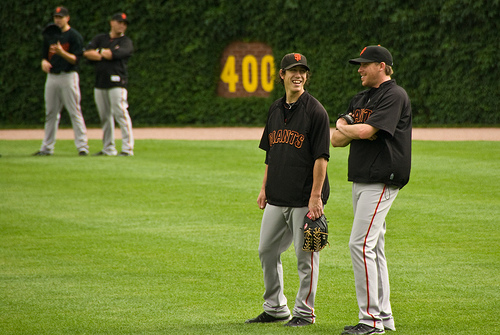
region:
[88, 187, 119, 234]
section of a field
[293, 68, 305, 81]
face of a boy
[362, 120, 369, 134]
part of an elbow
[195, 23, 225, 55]
part of a fence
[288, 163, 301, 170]
part of a jersey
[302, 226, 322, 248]
part of a glove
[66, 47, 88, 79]
part of a trouser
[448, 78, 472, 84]
bottom of a plant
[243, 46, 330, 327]
person in baseball uniform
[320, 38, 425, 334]
person in baseball uniform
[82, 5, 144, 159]
person in baseball uniform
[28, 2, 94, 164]
person in baseball uniform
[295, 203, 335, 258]
black leather baseball glove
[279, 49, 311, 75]
black hat with orange logo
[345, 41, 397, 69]
black hat with orange logo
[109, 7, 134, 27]
black hat with orange logo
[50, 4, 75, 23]
black hat with orange logo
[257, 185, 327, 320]
pair of grey baseball pants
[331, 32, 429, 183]
a man folding his arms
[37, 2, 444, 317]
four baseball players standing in field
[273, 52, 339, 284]
a man holding a baseball glove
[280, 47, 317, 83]
a man wearing a black cap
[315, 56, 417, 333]
a man wearing grey pants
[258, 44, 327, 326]
a man wearing grey pants with a red stripe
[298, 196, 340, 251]
a black and brown baseball glove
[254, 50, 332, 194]
a man wearing a black shirt with orange letters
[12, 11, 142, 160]
two men standing next to each other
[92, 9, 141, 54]
a man with his head turned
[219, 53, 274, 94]
yellow number on wall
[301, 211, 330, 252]
player holding black and brown glove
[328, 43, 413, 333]
player standing with arms folded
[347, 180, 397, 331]
player wearing gray pants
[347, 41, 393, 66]
player wearing black and orange cap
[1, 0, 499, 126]
green ivy growing on wall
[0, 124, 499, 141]
brown warning track near wall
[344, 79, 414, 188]
player wearing black and orange jacket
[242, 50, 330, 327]
player smiling at other player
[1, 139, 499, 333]
green outfield grass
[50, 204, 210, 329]
The grass is growing.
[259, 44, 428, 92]
They are wearing black hats.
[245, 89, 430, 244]
They have black shirts.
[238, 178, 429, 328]
Their pants are grey.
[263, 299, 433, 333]
They are wearing black shoes.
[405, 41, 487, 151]
The vines are leafy.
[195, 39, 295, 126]
The sign has yellow numbers.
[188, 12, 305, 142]
the sign is brown.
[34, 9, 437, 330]
They are playing baseball.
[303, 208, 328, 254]
She is holding a mitt.